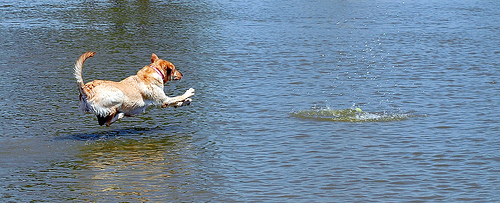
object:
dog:
[73, 52, 196, 127]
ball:
[356, 108, 362, 112]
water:
[0, 0, 500, 202]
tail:
[74, 51, 95, 85]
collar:
[150, 66, 166, 84]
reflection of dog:
[78, 139, 175, 200]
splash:
[330, 108, 410, 122]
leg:
[106, 111, 124, 126]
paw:
[186, 88, 196, 96]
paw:
[184, 99, 192, 103]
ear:
[167, 65, 174, 75]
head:
[151, 53, 183, 80]